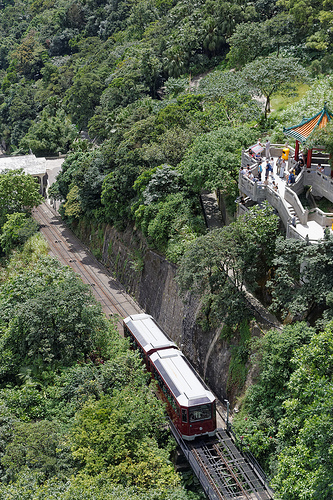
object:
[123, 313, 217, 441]
train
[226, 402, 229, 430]
pole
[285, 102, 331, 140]
roof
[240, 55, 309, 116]
tree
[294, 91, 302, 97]
leaf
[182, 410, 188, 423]
window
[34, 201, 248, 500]
track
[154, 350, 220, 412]
top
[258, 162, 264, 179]
person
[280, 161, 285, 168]
jacket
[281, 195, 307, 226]
steps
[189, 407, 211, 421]
windshield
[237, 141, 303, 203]
platform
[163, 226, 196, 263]
bush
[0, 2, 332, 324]
hillside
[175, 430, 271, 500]
bridge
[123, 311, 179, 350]
roof